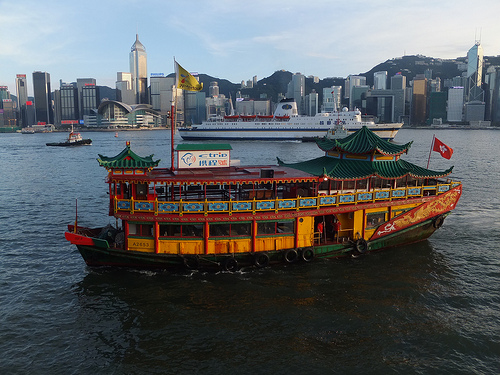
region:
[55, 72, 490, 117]
mountains behind the city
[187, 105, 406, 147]
yacht is on the water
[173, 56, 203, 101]
the flag is yellow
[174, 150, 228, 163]
the sign is white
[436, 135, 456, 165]
the flag is red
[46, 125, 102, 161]
the tug boat in the water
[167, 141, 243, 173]
dolphin sign on top of a boat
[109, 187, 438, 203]
blue and yellow railing on the erry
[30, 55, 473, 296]
Asian ferry on the water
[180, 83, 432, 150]
white small cruise ship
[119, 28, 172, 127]
tallest building near the water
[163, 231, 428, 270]
rubber tires used as bumpers for the boat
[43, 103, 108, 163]
little tug boat on the water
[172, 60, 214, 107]
yellow flag on the ferry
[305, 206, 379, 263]
two man in red near the entry of the boat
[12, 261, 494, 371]
calm water of this body of water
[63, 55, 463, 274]
a large multi colored boat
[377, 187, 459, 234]
a gold dragon breathing smoke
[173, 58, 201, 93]
a yellow flag with writing on it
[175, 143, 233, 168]
a white sign with writing and a dolphin on it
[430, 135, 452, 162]
a red and white flag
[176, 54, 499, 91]
three hills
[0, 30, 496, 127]
a city skyline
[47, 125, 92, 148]
a small white and black tug boat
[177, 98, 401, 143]
a white, red, and black boat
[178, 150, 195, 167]
a dolphin symbol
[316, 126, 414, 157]
A green roof on a boat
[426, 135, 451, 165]
A red flag on a boat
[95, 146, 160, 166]
A green roof on a boat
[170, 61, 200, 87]
A yellow flag on a boat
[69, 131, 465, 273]
A boat floating in water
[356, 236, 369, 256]
A black tire on a boat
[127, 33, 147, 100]
A tall building in a city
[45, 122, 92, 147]
A boat floating in water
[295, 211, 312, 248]
A yellow door on a boat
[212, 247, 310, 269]
A row of tires on a boat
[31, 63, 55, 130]
This is a tall building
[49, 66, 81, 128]
This is a tall building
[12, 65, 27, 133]
This is a tall building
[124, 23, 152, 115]
This is a tall building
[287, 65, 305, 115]
This is a tall building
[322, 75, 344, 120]
This is a tall building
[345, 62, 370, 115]
This is a tall building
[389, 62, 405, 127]
This is a tall building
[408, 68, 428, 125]
This is a tall building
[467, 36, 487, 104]
This is a tall building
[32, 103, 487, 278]
Boat on the river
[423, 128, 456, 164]
flag on the boat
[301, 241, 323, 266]
black tire on the side of the boar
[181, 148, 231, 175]
advertisement on the boat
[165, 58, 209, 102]
yellow flag on the boat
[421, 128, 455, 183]
red flag on the boat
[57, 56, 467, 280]
boat on the water